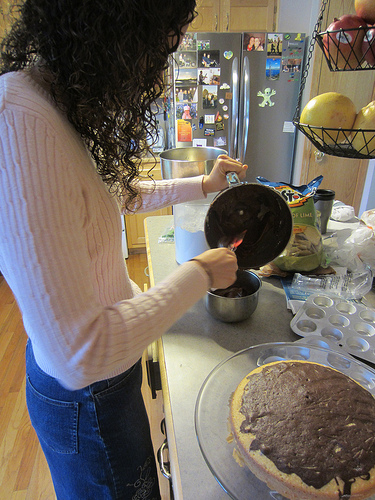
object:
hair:
[0, 1, 199, 210]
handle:
[239, 55, 253, 163]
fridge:
[170, 32, 308, 186]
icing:
[213, 279, 253, 295]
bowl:
[204, 269, 264, 321]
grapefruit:
[299, 91, 357, 143]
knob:
[314, 150, 325, 162]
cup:
[312, 188, 335, 235]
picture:
[243, 32, 266, 51]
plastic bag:
[320, 226, 374, 281]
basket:
[293, 122, 374, 157]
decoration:
[257, 87, 276, 108]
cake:
[232, 359, 374, 498]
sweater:
[0, 66, 210, 391]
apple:
[320, 16, 367, 69]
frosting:
[204, 185, 293, 273]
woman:
[0, 3, 241, 498]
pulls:
[159, 442, 172, 478]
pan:
[289, 290, 374, 366]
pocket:
[24, 379, 78, 459]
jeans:
[22, 340, 161, 499]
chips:
[304, 225, 322, 244]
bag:
[255, 171, 328, 275]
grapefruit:
[352, 100, 373, 158]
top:
[143, 209, 373, 499]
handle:
[143, 348, 161, 401]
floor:
[2, 202, 175, 499]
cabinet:
[187, 1, 278, 34]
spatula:
[230, 229, 248, 250]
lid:
[312, 188, 336, 203]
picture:
[265, 58, 280, 81]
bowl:
[203, 174, 293, 270]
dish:
[195, 344, 373, 499]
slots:
[297, 319, 317, 331]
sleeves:
[0, 108, 213, 391]